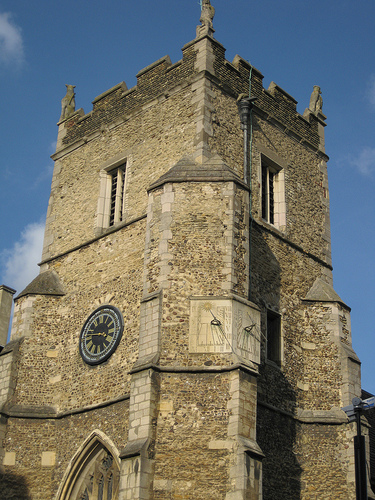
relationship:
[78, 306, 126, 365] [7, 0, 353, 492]
clock on tower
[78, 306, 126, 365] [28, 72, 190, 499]
clock on side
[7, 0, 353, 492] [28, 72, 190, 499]
tower has a side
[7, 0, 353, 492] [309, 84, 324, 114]
tower has statue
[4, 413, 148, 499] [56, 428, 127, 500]
wall has an archway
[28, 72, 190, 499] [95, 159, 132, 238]
wall has a window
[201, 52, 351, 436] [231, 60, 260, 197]
side has a gutter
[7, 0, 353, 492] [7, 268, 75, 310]
tower has a roof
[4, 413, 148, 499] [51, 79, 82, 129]
wall has a statue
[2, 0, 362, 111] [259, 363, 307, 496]
sunlight has a shadow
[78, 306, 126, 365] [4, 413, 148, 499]
clock on wall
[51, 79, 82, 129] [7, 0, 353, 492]
statue on tower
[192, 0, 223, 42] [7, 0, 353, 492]
statue on tower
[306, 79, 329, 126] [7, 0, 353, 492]
statue on tower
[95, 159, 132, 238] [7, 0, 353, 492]
window on tower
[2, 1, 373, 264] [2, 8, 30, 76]
sky has cloud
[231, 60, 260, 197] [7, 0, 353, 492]
gutter on tower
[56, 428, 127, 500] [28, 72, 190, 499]
window on side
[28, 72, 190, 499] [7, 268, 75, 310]
side has a roof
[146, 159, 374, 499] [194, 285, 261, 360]
wall has a scene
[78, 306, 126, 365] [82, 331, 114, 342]
clock has a time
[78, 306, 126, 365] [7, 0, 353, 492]
clock on a tower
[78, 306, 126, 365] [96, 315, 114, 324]
clock has numbers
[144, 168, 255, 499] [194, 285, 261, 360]
corner has a sundial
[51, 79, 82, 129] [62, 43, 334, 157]
statue on rooff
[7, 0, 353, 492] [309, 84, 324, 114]
tower has a statue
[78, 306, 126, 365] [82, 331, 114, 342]
clock has hands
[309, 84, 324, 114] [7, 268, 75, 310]
statue are on roof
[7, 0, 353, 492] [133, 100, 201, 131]
tower has brick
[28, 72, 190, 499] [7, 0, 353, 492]
side of tower